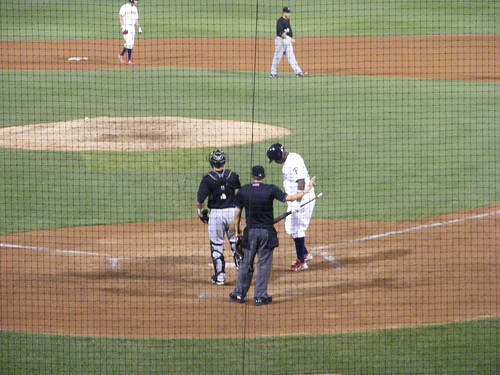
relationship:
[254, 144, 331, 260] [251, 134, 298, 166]
man wearing helmet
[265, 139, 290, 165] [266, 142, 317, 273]
head of a person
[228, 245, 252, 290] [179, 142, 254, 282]
leg of person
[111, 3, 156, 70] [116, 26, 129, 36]
man wearing glove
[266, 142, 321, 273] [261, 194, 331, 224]
man holding bat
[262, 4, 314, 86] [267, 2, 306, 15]
man wearing a hat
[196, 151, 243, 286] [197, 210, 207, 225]
man wearing baseball glove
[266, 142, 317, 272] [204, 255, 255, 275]
baseball player at home plate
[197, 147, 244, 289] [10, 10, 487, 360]
catcher at a baseball game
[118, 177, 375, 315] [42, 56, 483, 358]
pitcher's mound at a baseball field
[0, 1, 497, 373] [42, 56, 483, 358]
grass on baseball field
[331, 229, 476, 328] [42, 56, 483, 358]
dirt ground on baseball field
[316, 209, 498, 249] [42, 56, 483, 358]
chalk line on baseball field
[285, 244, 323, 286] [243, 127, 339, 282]
cleats on baseball player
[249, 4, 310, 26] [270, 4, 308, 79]
head of man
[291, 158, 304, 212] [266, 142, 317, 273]
arm of person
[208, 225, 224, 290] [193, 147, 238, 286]
leg of person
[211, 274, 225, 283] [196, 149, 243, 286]
feet of man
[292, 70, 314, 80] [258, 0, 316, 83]
feet of person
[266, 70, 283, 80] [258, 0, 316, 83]
feet of person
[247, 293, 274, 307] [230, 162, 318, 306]
feet of man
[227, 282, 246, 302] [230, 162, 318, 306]
feet of man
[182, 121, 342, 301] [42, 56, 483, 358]
players on baseball field